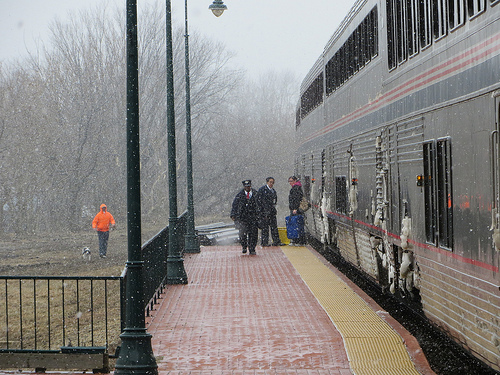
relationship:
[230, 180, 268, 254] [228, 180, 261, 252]
conductor in uniform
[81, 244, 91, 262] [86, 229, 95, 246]
dog on leash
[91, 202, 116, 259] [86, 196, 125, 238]
man with coat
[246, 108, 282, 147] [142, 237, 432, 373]
snow covered pavement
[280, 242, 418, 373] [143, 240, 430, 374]
stripe on ground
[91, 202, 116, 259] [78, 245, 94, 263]
man walking dog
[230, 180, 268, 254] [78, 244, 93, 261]
conductor walking dog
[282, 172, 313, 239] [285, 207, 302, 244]
woman holding suitcase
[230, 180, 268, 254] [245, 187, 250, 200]
conductor wearing tie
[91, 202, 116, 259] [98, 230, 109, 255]
man has pants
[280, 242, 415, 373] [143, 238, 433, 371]
stripe on platform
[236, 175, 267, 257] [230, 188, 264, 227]
conductor has coat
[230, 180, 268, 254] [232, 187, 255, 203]
conductor wearing a tie